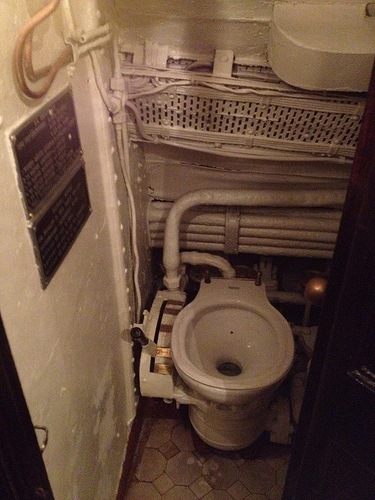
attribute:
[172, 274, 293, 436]
toilet — white, porcelain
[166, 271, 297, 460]
toilet — white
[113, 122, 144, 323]
wires — white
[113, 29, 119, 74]
pipe — fitting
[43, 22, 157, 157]
copper — exposed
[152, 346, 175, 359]
plate — copper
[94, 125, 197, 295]
wires — white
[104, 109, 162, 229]
wires — white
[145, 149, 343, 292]
pipe — white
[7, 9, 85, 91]
pipe — copper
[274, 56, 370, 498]
door — open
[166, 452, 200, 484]
tile — dirty, beige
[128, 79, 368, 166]
screen — white